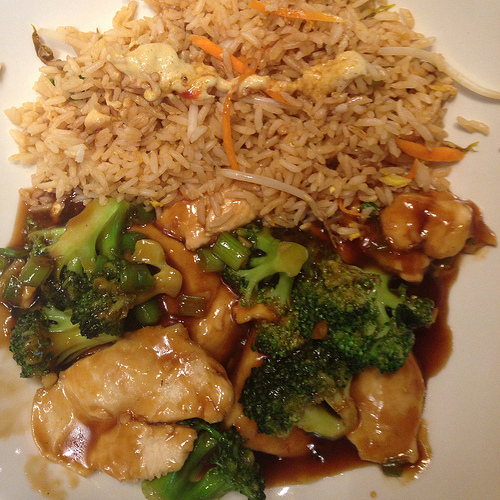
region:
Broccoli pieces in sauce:
[18, 179, 428, 469]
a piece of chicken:
[16, 325, 244, 491]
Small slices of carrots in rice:
[185, 43, 315, 187]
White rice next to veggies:
[7, 26, 462, 243]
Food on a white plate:
[8, 6, 470, 499]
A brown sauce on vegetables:
[18, 190, 475, 443]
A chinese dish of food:
[34, 68, 433, 428]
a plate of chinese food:
[28, 35, 465, 465]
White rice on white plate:
[23, 46, 470, 246]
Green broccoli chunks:
[202, 223, 423, 421]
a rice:
[76, 46, 416, 267]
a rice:
[110, 22, 319, 347]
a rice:
[116, 54, 248, 216]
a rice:
[161, 89, 333, 274]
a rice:
[251, 183, 351, 304]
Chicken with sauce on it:
[133, 317, 293, 497]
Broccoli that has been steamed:
[250, 345, 372, 437]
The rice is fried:
[71, 47, 148, 154]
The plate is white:
[3, 434, 26, 495]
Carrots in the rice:
[210, 56, 289, 181]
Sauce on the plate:
[361, 486, 383, 498]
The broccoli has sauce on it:
[249, 338, 393, 498]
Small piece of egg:
[367, 163, 418, 204]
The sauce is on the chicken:
[52, 383, 108, 434]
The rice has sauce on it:
[56, 98, 303, 192]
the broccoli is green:
[251, 356, 373, 441]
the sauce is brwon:
[295, 457, 357, 476]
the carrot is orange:
[213, 71, 260, 182]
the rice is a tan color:
[283, 133, 359, 182]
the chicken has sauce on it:
[68, 344, 200, 410]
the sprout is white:
[214, 160, 344, 228]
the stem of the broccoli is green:
[56, 205, 139, 257]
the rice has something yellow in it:
[350, 156, 443, 214]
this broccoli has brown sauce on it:
[7, 313, 82, 390]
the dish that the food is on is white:
[438, 392, 497, 490]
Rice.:
[250, 109, 356, 164]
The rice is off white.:
[246, 104, 363, 178]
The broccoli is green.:
[6, 214, 133, 342]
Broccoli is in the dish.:
[15, 205, 150, 356]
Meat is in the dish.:
[81, 344, 202, 451]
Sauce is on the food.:
[379, 263, 476, 376]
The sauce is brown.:
[410, 256, 480, 373]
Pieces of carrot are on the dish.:
[200, 70, 250, 184]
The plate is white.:
[1, 1, 496, 498]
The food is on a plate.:
[2, 0, 498, 497]